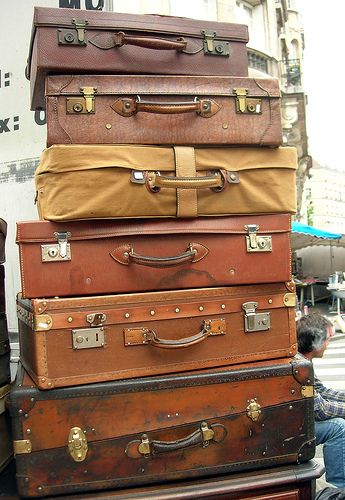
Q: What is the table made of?
A: Wood.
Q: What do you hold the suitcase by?
A: Handle.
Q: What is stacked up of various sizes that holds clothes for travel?
A: Suitcases.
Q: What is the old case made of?
A: Leather.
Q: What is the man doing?
A: Sitting.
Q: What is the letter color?
A: Black.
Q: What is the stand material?
A: Wood.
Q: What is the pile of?
A: Suitcases.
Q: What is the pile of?
A: Suitcases.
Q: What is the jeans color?
A: Blue.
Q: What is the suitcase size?
A: Small.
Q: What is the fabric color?
A: Tan.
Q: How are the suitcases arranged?
A: From smallest to largest.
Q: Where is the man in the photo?
A: Sitting on the right.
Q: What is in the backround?
A: A tall building.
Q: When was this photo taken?
A: Day time.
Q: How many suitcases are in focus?
A: Six.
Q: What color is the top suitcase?
A: Brown.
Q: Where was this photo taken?
A: Hotel.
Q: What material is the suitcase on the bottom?
A: Wood.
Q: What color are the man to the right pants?
A: Blue.